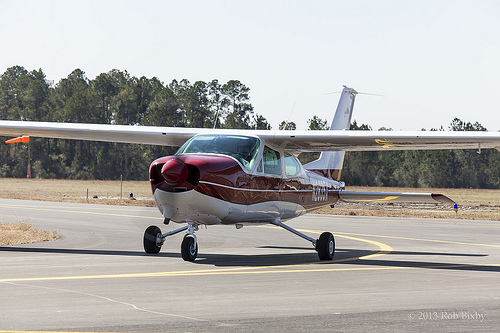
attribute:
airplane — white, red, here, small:
[0, 85, 500, 261]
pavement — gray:
[2, 196, 499, 332]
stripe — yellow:
[1, 226, 499, 286]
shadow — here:
[0, 245, 500, 273]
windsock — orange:
[5, 134, 32, 145]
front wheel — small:
[180, 232, 200, 263]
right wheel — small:
[143, 224, 162, 256]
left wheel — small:
[317, 232, 335, 263]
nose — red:
[160, 159, 189, 184]